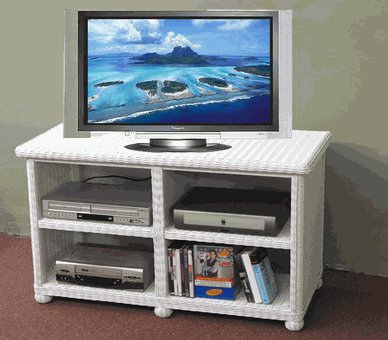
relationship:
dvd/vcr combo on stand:
[40, 180, 151, 226] [13, 120, 331, 330]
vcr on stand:
[50, 241, 156, 293] [13, 120, 331, 330]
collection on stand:
[165, 239, 279, 304] [13, 120, 331, 330]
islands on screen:
[92, 41, 258, 115] [41, 4, 313, 162]